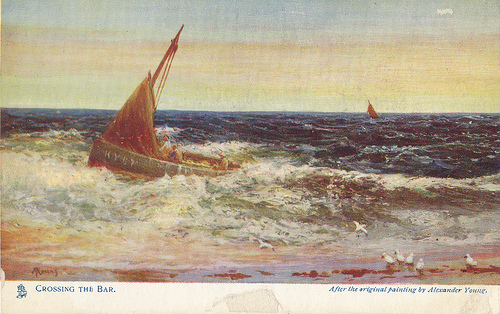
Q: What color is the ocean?
A: Blue, white, green, gray, and yellow.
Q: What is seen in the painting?
A: Two sailboats on the ocean.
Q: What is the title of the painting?
A: "Crossing The Bar".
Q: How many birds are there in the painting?
A: Seven.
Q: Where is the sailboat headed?
A: To the left.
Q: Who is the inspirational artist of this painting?
A: Alexander Young.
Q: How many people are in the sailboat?
A: Three.